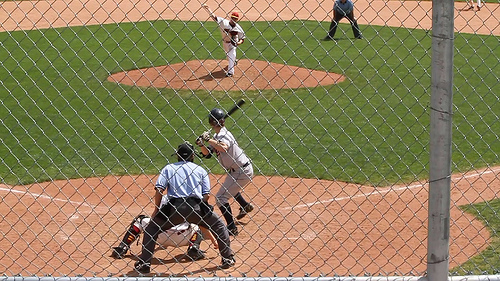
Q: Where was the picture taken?
A: A baseball game.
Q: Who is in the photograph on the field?
A: The baseball players and umpire.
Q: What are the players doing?
A: Playing baseball.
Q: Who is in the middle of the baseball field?
A: The pitcher.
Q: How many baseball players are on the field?
A: Three.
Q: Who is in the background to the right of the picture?
A: The referee.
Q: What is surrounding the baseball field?
A: A fence.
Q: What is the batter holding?
A: A bat.